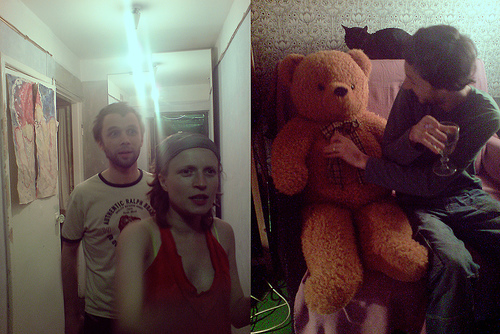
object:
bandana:
[152, 132, 221, 177]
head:
[153, 129, 223, 217]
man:
[322, 23, 500, 334]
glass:
[431, 121, 460, 178]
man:
[53, 95, 165, 334]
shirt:
[57, 166, 164, 319]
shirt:
[124, 206, 238, 334]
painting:
[5, 73, 37, 206]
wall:
[0, 0, 148, 334]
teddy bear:
[262, 42, 433, 319]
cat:
[338, 22, 413, 60]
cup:
[429, 117, 460, 176]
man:
[56, 100, 172, 334]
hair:
[91, 99, 146, 150]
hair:
[145, 132, 224, 233]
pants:
[395, 186, 500, 334]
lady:
[112, 132, 258, 332]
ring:
[330, 144, 339, 153]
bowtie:
[318, 119, 370, 188]